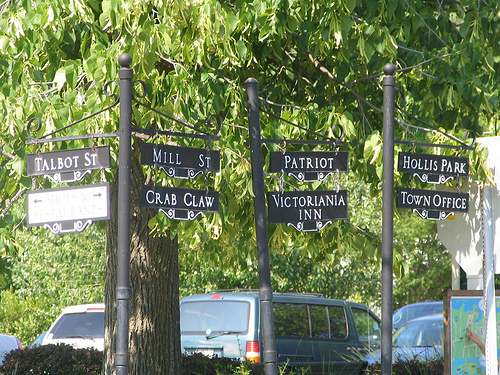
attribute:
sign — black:
[24, 143, 113, 182]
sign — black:
[136, 138, 227, 180]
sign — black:
[136, 182, 223, 223]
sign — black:
[267, 146, 352, 185]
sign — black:
[267, 187, 351, 237]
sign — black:
[394, 150, 473, 192]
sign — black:
[395, 185, 471, 224]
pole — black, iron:
[103, 50, 137, 374]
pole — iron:
[238, 74, 286, 375]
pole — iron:
[373, 59, 402, 374]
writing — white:
[32, 153, 100, 170]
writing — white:
[150, 146, 215, 175]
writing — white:
[143, 187, 214, 211]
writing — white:
[281, 154, 335, 173]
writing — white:
[270, 189, 346, 226]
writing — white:
[400, 154, 469, 176]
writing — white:
[400, 187, 468, 213]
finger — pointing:
[467, 327, 476, 338]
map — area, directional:
[446, 290, 500, 374]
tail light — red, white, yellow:
[245, 339, 259, 367]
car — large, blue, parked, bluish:
[167, 288, 400, 374]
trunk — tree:
[97, 120, 189, 374]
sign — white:
[24, 180, 115, 240]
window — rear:
[47, 308, 114, 350]